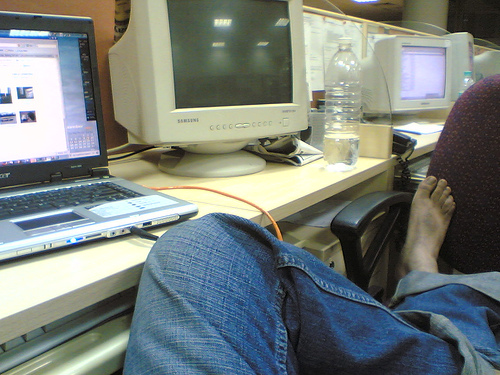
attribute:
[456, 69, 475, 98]
bottle — clear, plastic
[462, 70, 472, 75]
cap — green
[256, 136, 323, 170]
newspaper — folded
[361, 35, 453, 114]
monitor — old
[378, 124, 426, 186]
phone — land line, black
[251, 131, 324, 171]
paper — folded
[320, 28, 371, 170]
bottle — clear, plastic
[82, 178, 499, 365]
jeans — blue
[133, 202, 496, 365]
jeans — blue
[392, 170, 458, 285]
barefoot — propped up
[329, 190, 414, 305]
handle — black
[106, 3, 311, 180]
computer monitor — tan, gray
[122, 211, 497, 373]
jeans — blue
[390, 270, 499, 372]
cuffs — rolled up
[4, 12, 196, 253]
laptop — open, silver and black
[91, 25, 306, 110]
monitor — old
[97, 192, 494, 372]
pants — denim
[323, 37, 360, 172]
bottle — partially filled, water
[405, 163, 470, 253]
person — barefoot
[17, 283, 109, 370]
keyboard — white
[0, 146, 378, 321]
desktop — old, white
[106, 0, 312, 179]
computer — white, old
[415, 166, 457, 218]
toes — dirty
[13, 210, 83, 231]
trackpad — black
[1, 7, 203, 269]
laptop — open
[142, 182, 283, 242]
cable — yellow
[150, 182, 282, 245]
wire — orange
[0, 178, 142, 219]
keys — black